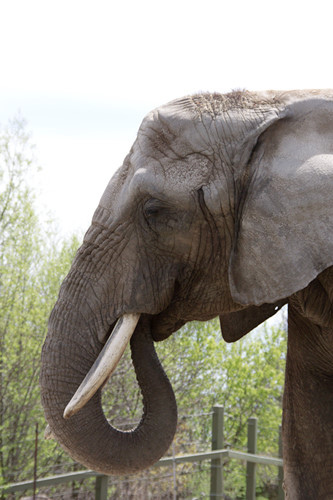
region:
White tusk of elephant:
[59, 309, 156, 421]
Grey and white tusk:
[64, 309, 151, 421]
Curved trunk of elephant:
[38, 207, 179, 476]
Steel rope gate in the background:
[0, 401, 283, 498]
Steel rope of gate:
[177, 405, 211, 427]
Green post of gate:
[208, 396, 225, 499]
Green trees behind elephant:
[1, 121, 281, 498]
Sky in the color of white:
[2, 0, 326, 233]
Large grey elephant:
[35, 84, 329, 499]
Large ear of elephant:
[227, 98, 331, 314]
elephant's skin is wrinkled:
[68, 216, 202, 364]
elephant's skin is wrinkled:
[75, 230, 163, 337]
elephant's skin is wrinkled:
[39, 232, 151, 372]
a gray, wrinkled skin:
[68, 247, 167, 336]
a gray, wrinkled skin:
[44, 258, 122, 344]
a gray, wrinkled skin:
[45, 259, 162, 370]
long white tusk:
[57, 305, 159, 432]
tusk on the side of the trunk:
[29, 274, 213, 487]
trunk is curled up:
[30, 272, 205, 489]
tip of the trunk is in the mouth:
[120, 317, 164, 354]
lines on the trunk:
[37, 278, 200, 476]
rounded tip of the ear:
[219, 331, 238, 347]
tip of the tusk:
[62, 407, 77, 420]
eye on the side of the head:
[144, 199, 167, 220]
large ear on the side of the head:
[228, 94, 332, 304]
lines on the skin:
[144, 123, 190, 164]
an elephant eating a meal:
[88, 100, 323, 326]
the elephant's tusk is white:
[43, 297, 168, 429]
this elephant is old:
[37, 106, 264, 348]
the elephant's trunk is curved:
[31, 274, 206, 479]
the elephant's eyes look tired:
[82, 166, 195, 256]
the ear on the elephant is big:
[198, 99, 332, 294]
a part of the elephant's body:
[262, 295, 327, 450]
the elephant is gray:
[129, 105, 288, 296]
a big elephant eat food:
[64, 110, 289, 348]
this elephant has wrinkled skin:
[90, 86, 313, 296]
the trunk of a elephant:
[22, 259, 168, 470]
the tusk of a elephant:
[52, 298, 162, 416]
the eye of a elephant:
[110, 190, 171, 245]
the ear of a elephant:
[197, 182, 309, 338]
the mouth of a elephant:
[121, 259, 204, 380]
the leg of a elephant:
[259, 339, 327, 490]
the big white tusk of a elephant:
[44, 296, 183, 443]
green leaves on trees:
[119, 352, 252, 429]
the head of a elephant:
[27, 199, 293, 479]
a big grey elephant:
[49, 170, 253, 428]